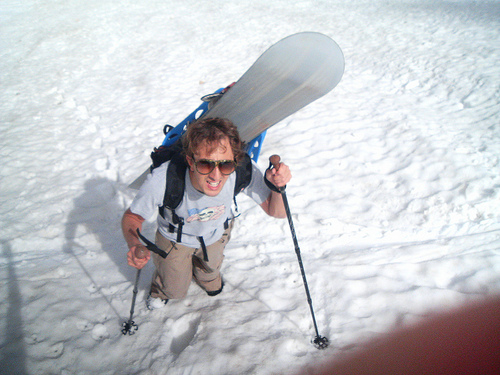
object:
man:
[121, 113, 294, 309]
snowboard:
[127, 30, 346, 191]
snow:
[0, 0, 499, 375]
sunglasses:
[191, 158, 237, 175]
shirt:
[128, 158, 273, 250]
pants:
[148, 218, 235, 299]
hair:
[180, 116, 246, 170]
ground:
[0, 0, 498, 372]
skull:
[186, 204, 225, 224]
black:
[280, 186, 320, 338]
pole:
[268, 154, 330, 350]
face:
[193, 143, 235, 196]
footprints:
[408, 190, 458, 214]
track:
[0, 220, 500, 276]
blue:
[176, 128, 180, 131]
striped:
[226, 57, 323, 134]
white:
[86, 63, 134, 101]